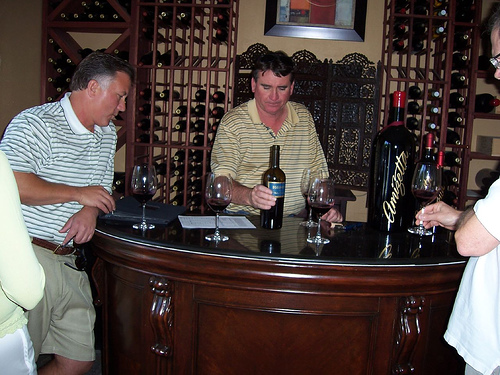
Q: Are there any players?
A: No, there are no players.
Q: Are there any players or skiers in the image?
A: No, there are no players or skiers.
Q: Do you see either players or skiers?
A: No, there are no players or skiers.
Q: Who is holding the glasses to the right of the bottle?
A: The man is holding the glasses.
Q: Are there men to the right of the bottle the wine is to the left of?
A: Yes, there is a man to the right of the bottle.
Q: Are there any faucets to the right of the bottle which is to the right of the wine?
A: No, there is a man to the right of the bottle.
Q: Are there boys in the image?
A: No, there are no boys.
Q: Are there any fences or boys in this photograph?
A: No, there are no boys or fences.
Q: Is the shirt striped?
A: Yes, the shirt is striped.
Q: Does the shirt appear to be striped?
A: Yes, the shirt is striped.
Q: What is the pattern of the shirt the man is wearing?
A: The shirt is striped.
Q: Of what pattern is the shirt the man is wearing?
A: The shirt is striped.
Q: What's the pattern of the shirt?
A: The shirt is striped.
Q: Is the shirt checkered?
A: No, the shirt is striped.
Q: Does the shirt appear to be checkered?
A: No, the shirt is striped.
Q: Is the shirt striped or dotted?
A: The shirt is striped.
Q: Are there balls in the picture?
A: No, there are no balls.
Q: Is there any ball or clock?
A: No, there are no balls or clocks.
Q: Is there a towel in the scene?
A: No, there are no towels.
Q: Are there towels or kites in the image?
A: No, there are no towels or kites.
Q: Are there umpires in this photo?
A: No, there are no umpires.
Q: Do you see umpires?
A: No, there are no umpires.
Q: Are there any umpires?
A: No, there are no umpires.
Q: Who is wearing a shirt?
A: The man is wearing a shirt.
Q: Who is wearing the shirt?
A: The man is wearing a shirt.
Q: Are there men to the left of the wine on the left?
A: Yes, there is a man to the left of the wine.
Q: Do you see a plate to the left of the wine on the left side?
A: No, there is a man to the left of the wine.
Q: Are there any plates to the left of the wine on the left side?
A: No, there is a man to the left of the wine.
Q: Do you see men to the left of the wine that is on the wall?
A: Yes, there is a man to the left of the wine.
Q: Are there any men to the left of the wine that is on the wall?
A: Yes, there is a man to the left of the wine.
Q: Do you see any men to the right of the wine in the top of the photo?
A: No, the man is to the left of the wine.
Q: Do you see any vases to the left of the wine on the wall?
A: No, there is a man to the left of the wine.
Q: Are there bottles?
A: Yes, there is a bottle.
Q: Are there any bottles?
A: Yes, there is a bottle.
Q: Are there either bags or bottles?
A: Yes, there is a bottle.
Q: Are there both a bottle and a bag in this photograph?
A: No, there is a bottle but no bags.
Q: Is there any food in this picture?
A: No, there is no food.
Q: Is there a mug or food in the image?
A: No, there are no food or mugs.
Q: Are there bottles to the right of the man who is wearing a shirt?
A: Yes, there is a bottle to the right of the man.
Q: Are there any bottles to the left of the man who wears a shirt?
A: No, the bottle is to the right of the man.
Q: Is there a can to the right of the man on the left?
A: No, there is a bottle to the right of the man.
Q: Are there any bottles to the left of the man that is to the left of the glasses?
A: Yes, there is a bottle to the left of the man.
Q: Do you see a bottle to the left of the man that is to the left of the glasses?
A: Yes, there is a bottle to the left of the man.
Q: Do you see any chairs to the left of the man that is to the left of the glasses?
A: No, there is a bottle to the left of the man.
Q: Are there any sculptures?
A: No, there are no sculptures.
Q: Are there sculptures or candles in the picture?
A: No, there are no sculptures or candles.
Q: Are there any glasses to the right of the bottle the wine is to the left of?
A: Yes, there are glasses to the right of the bottle.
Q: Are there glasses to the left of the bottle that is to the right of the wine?
A: No, the glasses are to the right of the bottle.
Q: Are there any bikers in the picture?
A: No, there are no bikers.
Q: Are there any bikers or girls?
A: No, there are no bikers or girls.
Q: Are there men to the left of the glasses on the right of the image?
A: Yes, there is a man to the left of the glasses.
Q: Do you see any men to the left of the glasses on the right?
A: Yes, there is a man to the left of the glasses.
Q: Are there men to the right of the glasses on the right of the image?
A: No, the man is to the left of the glasses.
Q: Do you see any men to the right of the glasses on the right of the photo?
A: No, the man is to the left of the glasses.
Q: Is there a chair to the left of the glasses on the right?
A: No, there is a man to the left of the glasses.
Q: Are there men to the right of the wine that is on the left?
A: Yes, there is a man to the right of the wine.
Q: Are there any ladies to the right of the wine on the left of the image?
A: No, there is a man to the right of the wine.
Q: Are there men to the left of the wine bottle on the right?
A: Yes, there is a man to the left of the wine bottle.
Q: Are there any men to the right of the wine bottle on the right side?
A: No, the man is to the left of the wine bottle.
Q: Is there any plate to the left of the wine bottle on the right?
A: No, there is a man to the left of the wine bottle.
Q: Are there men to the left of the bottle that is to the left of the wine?
A: Yes, there is a man to the left of the bottle.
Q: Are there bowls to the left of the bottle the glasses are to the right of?
A: No, there is a man to the left of the bottle.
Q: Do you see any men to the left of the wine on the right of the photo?
A: Yes, there is a man to the left of the wine.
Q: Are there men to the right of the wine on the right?
A: No, the man is to the left of the wine.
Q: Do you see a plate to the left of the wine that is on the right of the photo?
A: No, there is a man to the left of the wine.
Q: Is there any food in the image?
A: No, there is no food.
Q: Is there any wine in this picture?
A: Yes, there is wine.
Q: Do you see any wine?
A: Yes, there is wine.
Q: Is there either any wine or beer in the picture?
A: Yes, there is wine.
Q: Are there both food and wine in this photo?
A: No, there is wine but no food.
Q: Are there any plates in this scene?
A: No, there are no plates.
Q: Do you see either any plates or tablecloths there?
A: No, there are no plates or tablecloths.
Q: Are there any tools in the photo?
A: No, there are no tools.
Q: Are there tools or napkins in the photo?
A: No, there are no tools or napkins.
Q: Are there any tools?
A: No, there are no tools.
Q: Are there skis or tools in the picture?
A: No, there are no tools or skis.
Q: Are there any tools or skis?
A: No, there are no tools or skis.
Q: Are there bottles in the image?
A: Yes, there is a bottle.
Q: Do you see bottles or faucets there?
A: Yes, there is a bottle.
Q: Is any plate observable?
A: No, there are no plates.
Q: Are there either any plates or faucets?
A: No, there are no plates or faucets.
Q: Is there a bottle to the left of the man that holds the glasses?
A: Yes, there is a bottle to the left of the man.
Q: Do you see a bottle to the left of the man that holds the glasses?
A: Yes, there is a bottle to the left of the man.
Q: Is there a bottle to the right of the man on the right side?
A: No, the bottle is to the left of the man.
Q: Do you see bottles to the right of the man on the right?
A: No, the bottle is to the left of the man.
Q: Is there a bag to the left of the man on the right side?
A: No, there is a bottle to the left of the man.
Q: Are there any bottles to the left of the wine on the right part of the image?
A: Yes, there is a bottle to the left of the wine.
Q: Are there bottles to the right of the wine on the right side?
A: No, the bottle is to the left of the wine.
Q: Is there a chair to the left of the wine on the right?
A: No, there is a bottle to the left of the wine.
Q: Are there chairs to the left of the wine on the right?
A: No, there is a bottle to the left of the wine.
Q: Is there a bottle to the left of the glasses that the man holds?
A: Yes, there is a bottle to the left of the glasses.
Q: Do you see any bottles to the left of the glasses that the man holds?
A: Yes, there is a bottle to the left of the glasses.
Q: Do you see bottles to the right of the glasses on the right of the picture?
A: No, the bottle is to the left of the glasses.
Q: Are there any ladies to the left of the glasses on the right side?
A: No, there is a bottle to the left of the glasses.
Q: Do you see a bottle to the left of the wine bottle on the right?
A: Yes, there is a bottle to the left of the wine bottle.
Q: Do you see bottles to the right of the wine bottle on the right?
A: No, the bottle is to the left of the wine bottle.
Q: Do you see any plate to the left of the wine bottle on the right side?
A: No, there is a bottle to the left of the wine bottle.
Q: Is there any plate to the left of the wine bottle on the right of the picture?
A: No, there is a bottle to the left of the wine bottle.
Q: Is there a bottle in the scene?
A: Yes, there is a bottle.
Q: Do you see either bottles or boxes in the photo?
A: Yes, there is a bottle.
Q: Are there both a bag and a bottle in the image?
A: No, there is a bottle but no bags.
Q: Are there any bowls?
A: No, there are no bowls.